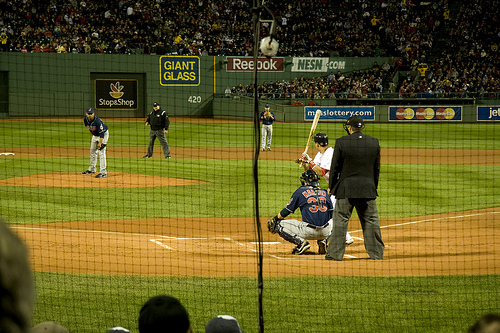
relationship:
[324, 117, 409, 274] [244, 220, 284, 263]
umpire standing near homeplate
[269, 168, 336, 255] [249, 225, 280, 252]
catcher standing by homebase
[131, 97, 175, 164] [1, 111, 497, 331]
umpire in field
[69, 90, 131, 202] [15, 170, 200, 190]
pitcher standing on mound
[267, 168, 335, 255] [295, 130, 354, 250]
catcher behind batter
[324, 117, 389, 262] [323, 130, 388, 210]
umpire wearing jacket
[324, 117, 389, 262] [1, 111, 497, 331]
umpire standing on field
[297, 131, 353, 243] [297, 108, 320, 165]
batter holding bat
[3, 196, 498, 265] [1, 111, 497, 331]
line painted on field